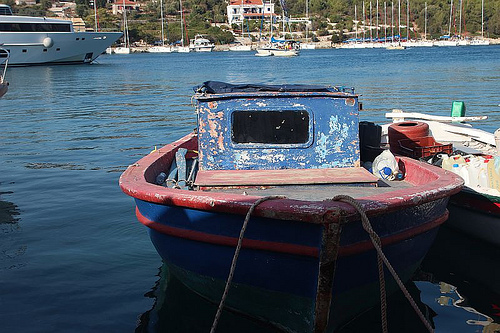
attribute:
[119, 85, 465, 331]
boat — blue, red, dilapidated, small, old, anchored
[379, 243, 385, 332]
rope — anchored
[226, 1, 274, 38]
house — red, white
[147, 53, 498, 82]
lake — large, calm, rippling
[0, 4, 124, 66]
yacht — white, large, traveling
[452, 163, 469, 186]
bottle — plastic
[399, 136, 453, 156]
red crate — plastic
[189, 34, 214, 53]
boat — white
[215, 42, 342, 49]
shore — sandy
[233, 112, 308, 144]
window — small